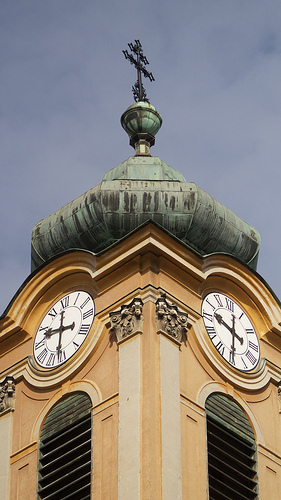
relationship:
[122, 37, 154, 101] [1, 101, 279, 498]
weather vane on building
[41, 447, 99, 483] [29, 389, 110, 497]
vents on window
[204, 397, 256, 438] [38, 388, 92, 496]
wood slats on window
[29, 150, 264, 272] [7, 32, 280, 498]
structure by building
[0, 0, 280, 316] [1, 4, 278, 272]
clouds in sky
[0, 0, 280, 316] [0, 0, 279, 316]
clouds in sky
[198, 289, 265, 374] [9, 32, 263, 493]
clock on tower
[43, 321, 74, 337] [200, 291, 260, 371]
hour hand on clock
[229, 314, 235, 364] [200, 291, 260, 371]
minute hand on clock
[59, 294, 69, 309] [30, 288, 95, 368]
roman numeral on clock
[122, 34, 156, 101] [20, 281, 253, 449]
weather vane on top of clock tower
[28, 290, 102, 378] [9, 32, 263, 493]
clock on tower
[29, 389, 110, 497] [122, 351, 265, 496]
window on tower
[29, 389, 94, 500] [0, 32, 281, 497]
window on building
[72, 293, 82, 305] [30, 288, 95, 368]
roman numeral on clock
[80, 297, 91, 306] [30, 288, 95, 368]
2 on clock